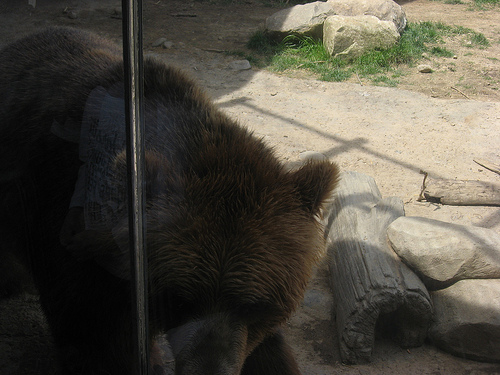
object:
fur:
[8, 28, 54, 72]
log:
[319, 167, 434, 359]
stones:
[258, 0, 326, 35]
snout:
[169, 335, 257, 374]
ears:
[285, 157, 338, 213]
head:
[49, 127, 334, 375]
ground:
[400, 5, 499, 128]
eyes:
[167, 292, 194, 321]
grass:
[270, 44, 300, 68]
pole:
[118, 0, 147, 365]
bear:
[0, 30, 329, 374]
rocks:
[434, 275, 500, 360]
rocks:
[321, 13, 400, 59]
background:
[190, 0, 498, 77]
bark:
[422, 174, 498, 205]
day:
[4, 4, 499, 283]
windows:
[157, 0, 500, 375]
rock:
[383, 212, 499, 280]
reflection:
[68, 63, 228, 357]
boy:
[71, 67, 205, 262]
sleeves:
[63, 124, 91, 212]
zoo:
[1, 0, 494, 370]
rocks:
[148, 37, 165, 50]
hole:
[370, 303, 421, 357]